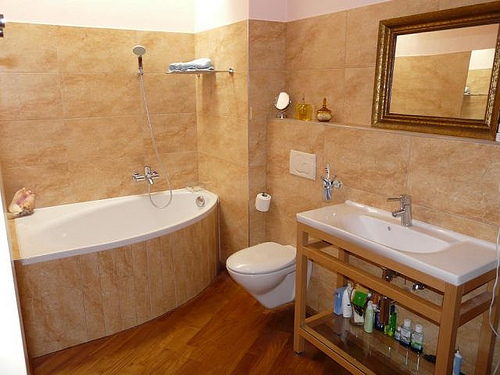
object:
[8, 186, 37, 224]
shell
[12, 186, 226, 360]
bathtub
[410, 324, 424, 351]
soaps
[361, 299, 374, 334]
shampoos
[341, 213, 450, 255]
sink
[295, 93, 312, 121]
oil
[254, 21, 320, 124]
corner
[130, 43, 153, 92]
shower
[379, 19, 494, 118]
mirror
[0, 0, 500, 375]
bathroom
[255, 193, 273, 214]
paper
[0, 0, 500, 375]
wall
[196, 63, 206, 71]
blue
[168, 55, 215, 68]
towel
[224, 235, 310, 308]
toilet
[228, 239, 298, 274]
sit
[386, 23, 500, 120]
reflections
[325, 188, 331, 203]
soap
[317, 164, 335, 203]
holder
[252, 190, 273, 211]
roll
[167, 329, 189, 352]
shine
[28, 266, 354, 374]
flooring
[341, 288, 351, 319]
personal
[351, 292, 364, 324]
products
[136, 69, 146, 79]
removeable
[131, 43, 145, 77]
head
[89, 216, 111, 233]
white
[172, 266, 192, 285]
tile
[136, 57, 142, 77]
handheld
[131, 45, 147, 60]
sprayer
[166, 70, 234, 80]
shelf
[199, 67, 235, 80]
rack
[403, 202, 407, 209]
silver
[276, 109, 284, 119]
stand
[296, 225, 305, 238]
wooden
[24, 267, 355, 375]
hardwood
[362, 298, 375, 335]
items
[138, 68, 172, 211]
chord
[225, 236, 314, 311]
european